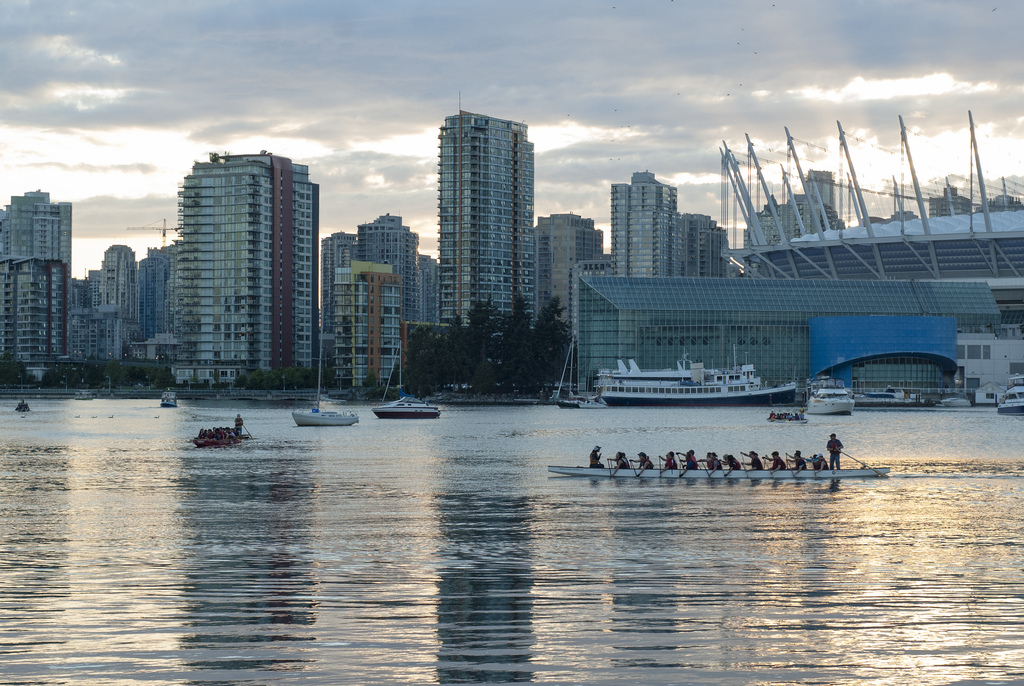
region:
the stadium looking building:
[691, 86, 1017, 274]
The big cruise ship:
[580, 356, 792, 418]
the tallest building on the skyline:
[430, 89, 551, 402]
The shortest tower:
[323, 249, 410, 404]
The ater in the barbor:
[2, 380, 1017, 681]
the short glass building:
[561, 253, 1007, 431]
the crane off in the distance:
[130, 221, 191, 248]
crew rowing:
[557, 427, 912, 497]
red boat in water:
[193, 408, 250, 457]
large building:
[166, 122, 319, 380]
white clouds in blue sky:
[459, 51, 505, 71]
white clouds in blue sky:
[582, 64, 621, 106]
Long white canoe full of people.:
[549, 411, 888, 506]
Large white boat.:
[590, 349, 794, 406]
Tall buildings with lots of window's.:
[25, 108, 1022, 397]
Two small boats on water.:
[293, 387, 442, 444]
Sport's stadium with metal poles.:
[710, 105, 1011, 282]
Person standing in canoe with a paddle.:
[824, 430, 870, 484]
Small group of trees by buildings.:
[417, 294, 577, 397]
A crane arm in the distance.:
[131, 212, 185, 236]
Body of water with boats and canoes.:
[12, 381, 1016, 675]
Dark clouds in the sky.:
[16, 4, 1018, 252]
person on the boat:
[804, 445, 827, 472]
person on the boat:
[756, 443, 795, 470]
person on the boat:
[580, 445, 606, 464]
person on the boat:
[605, 446, 632, 466]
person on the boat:
[655, 446, 681, 470]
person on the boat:
[687, 445, 711, 475]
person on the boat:
[225, 410, 248, 434]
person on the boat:
[792, 461, 815, 477]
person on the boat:
[699, 449, 725, 482]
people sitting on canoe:
[590, 433, 844, 469]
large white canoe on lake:
[550, 464, 892, 477]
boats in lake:
[9, 385, 1022, 483]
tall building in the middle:
[435, 105, 546, 334]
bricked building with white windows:
[325, 260, 409, 396]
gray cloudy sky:
[0, 3, 1016, 280]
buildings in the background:
[2, 107, 739, 387]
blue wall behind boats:
[808, 315, 965, 388]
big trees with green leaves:
[392, 293, 577, 396]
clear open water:
[5, 375, 1021, 679]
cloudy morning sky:
[7, 10, 1020, 263]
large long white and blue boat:
[580, 312, 818, 423]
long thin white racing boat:
[555, 432, 903, 491]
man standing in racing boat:
[817, 430, 862, 481]